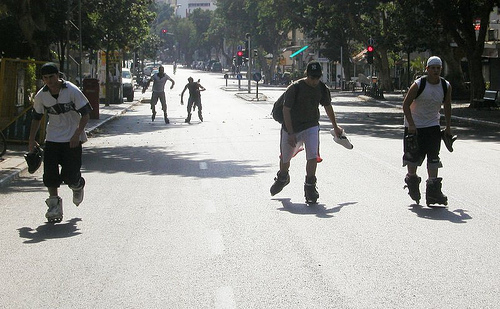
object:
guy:
[269, 61, 354, 210]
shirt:
[281, 80, 335, 132]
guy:
[402, 53, 457, 209]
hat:
[422, 55, 447, 63]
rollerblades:
[301, 183, 322, 208]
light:
[235, 49, 246, 67]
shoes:
[327, 126, 355, 151]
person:
[179, 76, 205, 122]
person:
[142, 66, 176, 125]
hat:
[306, 58, 322, 78]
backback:
[270, 96, 286, 121]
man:
[24, 60, 92, 224]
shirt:
[31, 84, 89, 143]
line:
[193, 155, 242, 306]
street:
[3, 65, 499, 307]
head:
[424, 54, 445, 79]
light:
[362, 46, 376, 65]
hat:
[38, 63, 58, 73]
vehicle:
[117, 64, 133, 98]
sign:
[252, 72, 263, 96]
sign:
[235, 72, 245, 92]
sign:
[224, 72, 230, 86]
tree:
[463, 0, 488, 106]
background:
[1, 2, 496, 124]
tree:
[361, 1, 395, 94]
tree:
[251, 4, 278, 88]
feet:
[298, 182, 320, 204]